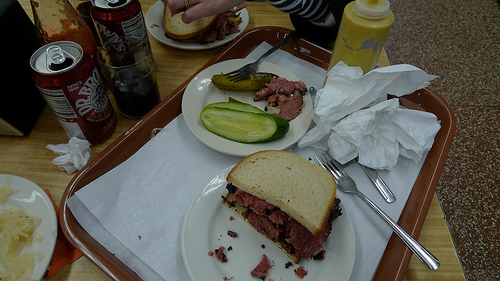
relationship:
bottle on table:
[32, 39, 118, 146] [4, 2, 454, 278]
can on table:
[87, 1, 153, 77] [4, 2, 454, 278]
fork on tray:
[313, 150, 442, 272] [59, 26, 453, 280]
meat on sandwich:
[223, 185, 332, 261] [220, 148, 342, 263]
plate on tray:
[180, 59, 312, 156] [59, 26, 453, 280]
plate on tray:
[180, 167, 357, 279] [59, 26, 453, 280]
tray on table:
[59, 26, 453, 280] [4, 2, 454, 278]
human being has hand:
[161, 0, 346, 29] [168, 0, 239, 23]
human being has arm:
[161, 0, 346, 29] [263, 0, 337, 30]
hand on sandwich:
[168, 0, 239, 23] [160, 0, 228, 44]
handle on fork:
[356, 192, 440, 272] [313, 150, 442, 272]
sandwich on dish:
[220, 148, 342, 263] [180, 163, 358, 280]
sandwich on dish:
[220, 148, 342, 263] [168, 158, 366, 279]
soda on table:
[24, 36, 107, 152] [4, 2, 454, 278]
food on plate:
[4, 187, 45, 279] [4, 165, 62, 279]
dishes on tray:
[201, 70, 342, 278] [59, 26, 453, 280]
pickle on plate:
[199, 97, 288, 144] [173, 53, 325, 165]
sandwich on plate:
[220, 148, 342, 263] [177, 182, 364, 280]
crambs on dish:
[208, 224, 278, 274] [168, 158, 366, 279]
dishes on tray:
[175, 51, 367, 278] [59, 26, 453, 280]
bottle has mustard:
[326, 1, 395, 85] [322, 0, 403, 67]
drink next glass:
[82, 0, 163, 85] [88, 29, 166, 119]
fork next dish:
[218, 28, 299, 83] [173, 51, 320, 158]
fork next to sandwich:
[313, 150, 442, 272] [222, 150, 333, 250]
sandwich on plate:
[220, 148, 342, 263] [180, 167, 357, 279]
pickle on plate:
[199, 97, 288, 144] [185, 57, 316, 152]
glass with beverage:
[94, 33, 164, 118] [112, 68, 159, 119]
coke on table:
[30, 39, 118, 149] [4, 2, 454, 278]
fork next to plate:
[313, 150, 442, 272] [180, 167, 357, 279]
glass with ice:
[94, 33, 164, 118] [105, 63, 142, 95]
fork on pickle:
[220, 28, 300, 78] [212, 68, 271, 88]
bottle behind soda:
[29, 3, 101, 66] [31, 39, 115, 146]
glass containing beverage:
[94, 33, 164, 118] [108, 66, 161, 120]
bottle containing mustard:
[322, 1, 395, 87] [320, 0, 396, 86]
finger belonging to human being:
[179, 5, 213, 25] [162, 0, 347, 49]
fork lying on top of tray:
[313, 150, 442, 272] [59, 26, 453, 280]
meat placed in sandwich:
[235, 185, 331, 258] [220, 148, 342, 263]